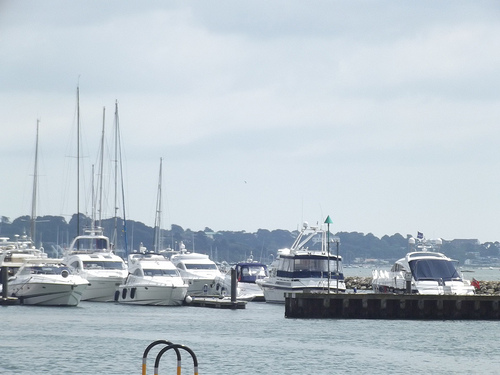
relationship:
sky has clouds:
[1, 0, 490, 235] [208, 14, 499, 159]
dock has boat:
[285, 291, 498, 321] [253, 220, 348, 302]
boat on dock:
[253, 220, 348, 302] [285, 291, 498, 321]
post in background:
[25, 82, 174, 258] [27, 53, 487, 273]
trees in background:
[1, 213, 499, 261] [27, 53, 487, 273]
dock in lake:
[285, 291, 498, 321] [6, 302, 497, 373]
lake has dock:
[6, 302, 497, 373] [285, 291, 498, 321]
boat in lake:
[253, 220, 348, 302] [6, 302, 497, 373]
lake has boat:
[6, 302, 497, 373] [253, 220, 348, 302]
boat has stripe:
[6, 260, 91, 310] [21, 291, 87, 300]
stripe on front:
[21, 291, 87, 300] [25, 274, 88, 307]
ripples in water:
[24, 315, 398, 373] [4, 311, 484, 373]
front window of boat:
[404, 257, 457, 280] [392, 243, 484, 335]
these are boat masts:
[18, 85, 178, 276] [23, 75, 186, 246]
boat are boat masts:
[63, 163, 125, 300] [23, 75, 186, 246]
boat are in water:
[6, 260, 91, 310] [1, 265, 498, 369]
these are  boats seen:
[14, 211, 438, 344] [35, 115, 455, 324]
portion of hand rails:
[151, 347, 194, 375] [138, 335, 200, 372]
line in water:
[35, 327, 482, 368] [210, 317, 499, 373]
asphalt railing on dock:
[279, 250, 476, 324] [167, 288, 481, 375]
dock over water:
[281, 289, 498, 321] [3, 323, 497, 370]